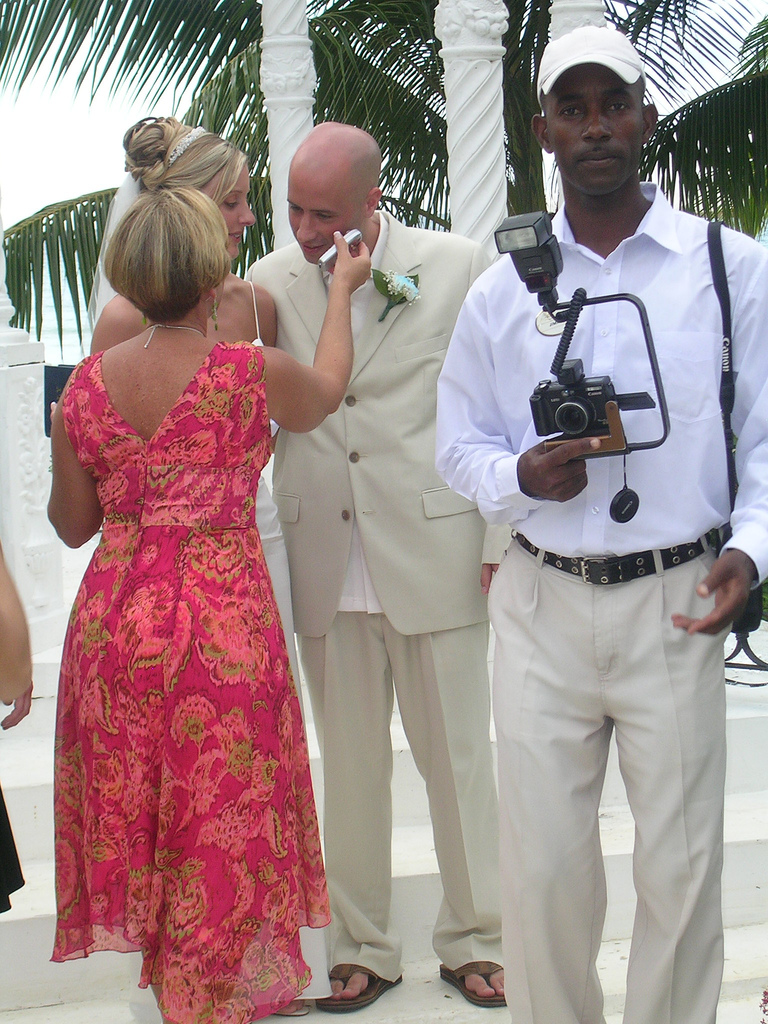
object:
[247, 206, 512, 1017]
suit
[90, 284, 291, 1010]
dress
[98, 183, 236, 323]
hair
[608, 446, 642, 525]
lens cap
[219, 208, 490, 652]
jacket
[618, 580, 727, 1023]
pant leg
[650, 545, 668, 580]
loop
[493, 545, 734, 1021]
pants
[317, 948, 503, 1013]
sandals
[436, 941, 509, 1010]
sandles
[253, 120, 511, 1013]
man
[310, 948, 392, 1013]
flip flops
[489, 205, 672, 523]
camera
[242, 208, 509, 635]
jacket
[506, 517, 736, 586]
belt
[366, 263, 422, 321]
flower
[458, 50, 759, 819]
man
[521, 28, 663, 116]
cap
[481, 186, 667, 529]
camera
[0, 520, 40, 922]
woman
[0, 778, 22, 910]
black dress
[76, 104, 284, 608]
woman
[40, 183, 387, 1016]
woman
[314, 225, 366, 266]
cellphone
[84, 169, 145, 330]
veil